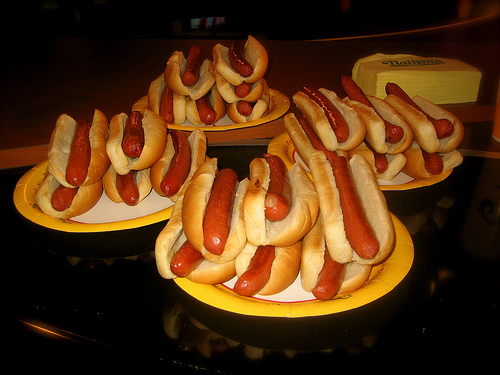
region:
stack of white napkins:
[351, 52, 481, 105]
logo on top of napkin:
[381, 55, 442, 70]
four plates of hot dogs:
[12, 35, 460, 320]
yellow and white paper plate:
[172, 202, 414, 317]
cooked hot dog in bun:
[312, 151, 394, 261]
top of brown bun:
[179, 157, 216, 250]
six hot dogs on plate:
[156, 150, 412, 315]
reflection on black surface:
[161, 297, 354, 362]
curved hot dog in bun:
[157, 127, 190, 194]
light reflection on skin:
[210, 233, 222, 248]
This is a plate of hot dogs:
[216, 153, 381, 303]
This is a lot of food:
[198, 196, 262, 271]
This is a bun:
[161, 181, 201, 225]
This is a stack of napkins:
[337, 59, 466, 97]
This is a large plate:
[283, 291, 345, 332]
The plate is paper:
[261, 304, 296, 357]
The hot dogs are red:
[215, 221, 261, 287]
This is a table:
[146, 266, 201, 373]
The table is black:
[78, 254, 146, 366]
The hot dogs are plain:
[156, 185, 233, 257]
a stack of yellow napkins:
[350, 52, 482, 104]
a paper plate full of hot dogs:
[171, 210, 413, 317]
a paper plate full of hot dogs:
[12, 154, 210, 232]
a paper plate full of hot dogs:
[267, 130, 453, 190]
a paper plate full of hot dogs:
[130, 87, 289, 131]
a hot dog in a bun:
[180, 156, 250, 263]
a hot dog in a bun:
[242, 153, 318, 247]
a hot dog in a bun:
[307, 150, 395, 265]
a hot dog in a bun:
[46, 108, 110, 187]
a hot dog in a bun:
[105, 108, 167, 175]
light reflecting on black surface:
[26, 310, 91, 341]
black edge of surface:
[78, 336, 149, 365]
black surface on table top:
[63, 255, 144, 303]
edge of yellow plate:
[191, 288, 290, 327]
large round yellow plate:
[158, 193, 418, 340]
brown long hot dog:
[329, 190, 386, 262]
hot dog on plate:
[239, 142, 324, 261]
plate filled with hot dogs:
[173, 142, 419, 304]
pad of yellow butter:
[358, 47, 484, 109]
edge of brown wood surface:
[14, 123, 41, 153]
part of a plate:
[381, 282, 391, 288]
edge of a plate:
[298, 302, 304, 305]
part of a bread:
[373, 200, 393, 233]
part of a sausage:
[272, 191, 279, 206]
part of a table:
[108, 304, 128, 333]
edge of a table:
[401, 320, 413, 331]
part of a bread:
[325, 193, 330, 220]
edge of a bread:
[289, 220, 295, 227]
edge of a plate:
[225, 289, 236, 297]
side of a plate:
[128, 218, 137, 228]